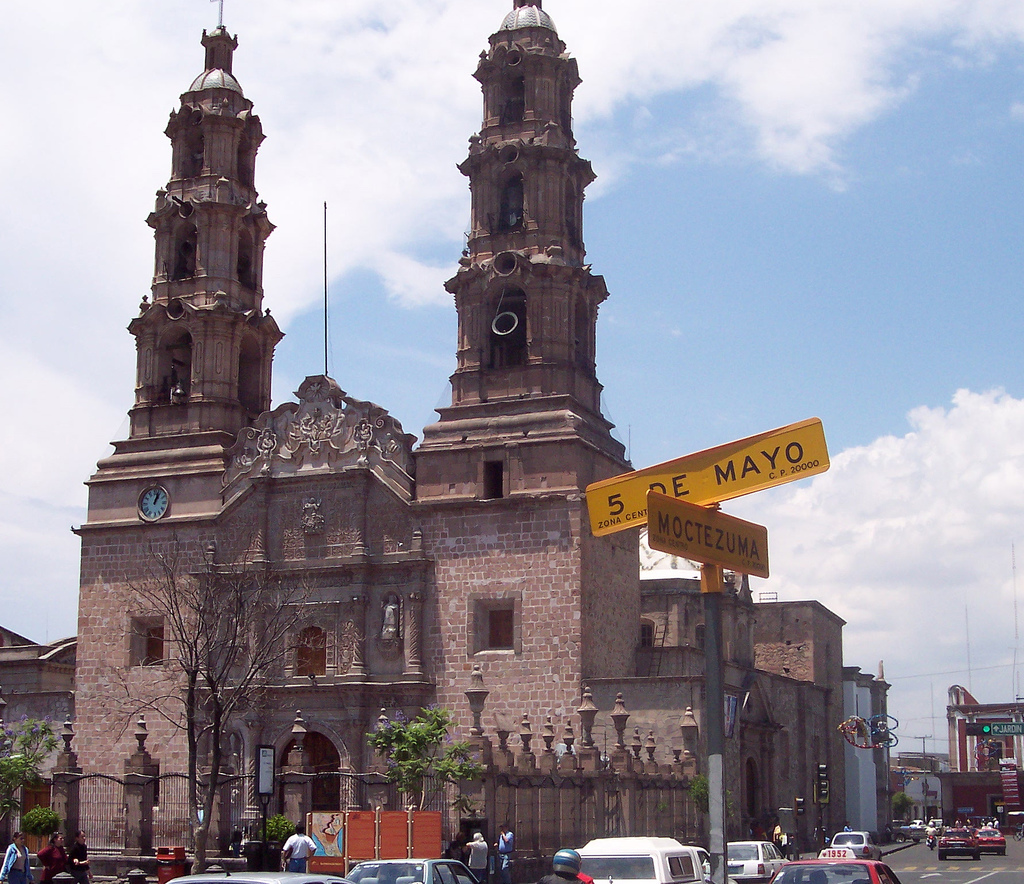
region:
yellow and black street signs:
[590, 399, 835, 606]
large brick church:
[124, 0, 647, 857]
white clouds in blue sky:
[797, 514, 832, 563]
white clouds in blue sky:
[942, 433, 999, 492]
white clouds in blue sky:
[891, 574, 975, 645]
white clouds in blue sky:
[768, 170, 908, 303]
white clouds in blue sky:
[755, 53, 853, 168]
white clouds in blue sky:
[351, 88, 416, 136]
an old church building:
[77, 0, 850, 870]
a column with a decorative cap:
[459, 664, 486, 881]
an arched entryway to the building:
[273, 726, 347, 813]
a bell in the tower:
[487, 281, 522, 376]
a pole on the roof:
[318, 199, 332, 383]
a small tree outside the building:
[374, 702, 448, 808]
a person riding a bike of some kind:
[917, 815, 944, 850]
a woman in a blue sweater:
[0, 830, 33, 882]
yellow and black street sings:
[562, 382, 848, 591]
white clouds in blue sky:
[29, 66, 94, 164]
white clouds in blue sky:
[23, 375, 91, 420]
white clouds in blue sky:
[263, 16, 374, 99]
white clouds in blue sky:
[298, 162, 387, 251]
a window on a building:
[164, 205, 197, 297]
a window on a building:
[145, 328, 197, 398]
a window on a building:
[126, 614, 162, 662]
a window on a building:
[292, 613, 332, 677]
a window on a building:
[463, 597, 525, 667]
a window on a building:
[492, 288, 530, 372]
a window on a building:
[501, 76, 533, 134]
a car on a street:
[818, 815, 875, 860]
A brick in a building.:
[486, 702, 505, 712]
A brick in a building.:
[508, 544, 528, 555]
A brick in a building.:
[528, 555, 549, 566]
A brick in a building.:
[555, 557, 571, 565]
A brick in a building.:
[594, 607, 608, 614]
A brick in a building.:
[540, 700, 547, 710]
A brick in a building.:
[95, 674, 111, 685]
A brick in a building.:
[98, 664, 112, 671]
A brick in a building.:
[148, 724, 165, 732]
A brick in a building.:
[142, 551, 156, 571]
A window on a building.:
[474, 599, 512, 653]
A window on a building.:
[490, 462, 504, 498]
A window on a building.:
[299, 624, 328, 675]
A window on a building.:
[141, 617, 161, 663]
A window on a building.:
[489, 294, 529, 370]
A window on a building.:
[501, 178, 524, 229]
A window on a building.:
[499, 67, 522, 124]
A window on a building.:
[187, 134, 201, 172]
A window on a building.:
[173, 212, 200, 283]